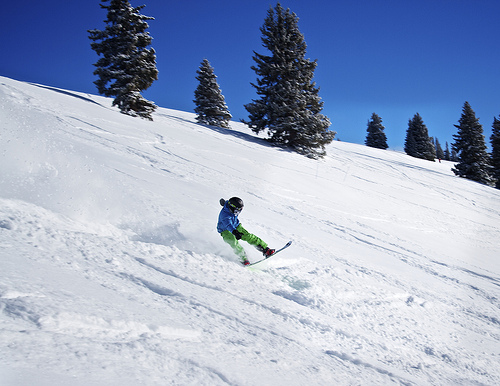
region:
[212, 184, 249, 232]
person is wearing helmet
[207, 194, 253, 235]
person's jacket is blue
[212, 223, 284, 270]
person's pants are green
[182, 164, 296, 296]
person is snowboarding downhill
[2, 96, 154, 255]
snow is being tossed in air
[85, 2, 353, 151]
trees are covered in snow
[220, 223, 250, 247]
person wearing black gloves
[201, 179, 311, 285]
person is leaning backwards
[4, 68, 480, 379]
ground is covered in snow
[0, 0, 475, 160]
the sky is clear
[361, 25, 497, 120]
the sky is cloudless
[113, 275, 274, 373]
the snow is white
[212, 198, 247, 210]
the helmet is black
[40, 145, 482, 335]
the slope is sloppy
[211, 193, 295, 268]
one leg is up in the air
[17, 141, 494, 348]
the hill is covered with snow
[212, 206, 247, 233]
the top is blue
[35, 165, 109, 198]
there is snow in the air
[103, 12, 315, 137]
trees are covered with snow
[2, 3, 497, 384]
the season is winter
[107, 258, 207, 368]
The snow is white.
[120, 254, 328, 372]
The snow is white.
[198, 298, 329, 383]
The snow is white.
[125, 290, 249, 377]
The snow is white.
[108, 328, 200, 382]
The snow is white.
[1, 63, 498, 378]
The snow is white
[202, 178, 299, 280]
Snowboarder is snowboarding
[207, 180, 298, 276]
Snowboarder wearing bright green pants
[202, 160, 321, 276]
Snowboarder wearing black helmet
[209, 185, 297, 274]
Snowboarder wearing blue jacket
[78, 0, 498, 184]
Trees on the slope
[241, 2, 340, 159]
The tree is large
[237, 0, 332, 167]
The large tree is green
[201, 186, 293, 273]
Snowboarder on the slope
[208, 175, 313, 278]
Snowboarder wearing red boots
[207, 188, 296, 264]
snowboarder in green pants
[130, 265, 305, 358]
snowboard tracks in the snow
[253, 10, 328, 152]
tree covered in snow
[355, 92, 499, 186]
many trees in a line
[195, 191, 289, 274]
snowboarder wearing black helmet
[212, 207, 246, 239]
snowboarder wearing blue jacket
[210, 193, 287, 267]
snowboarder on the snow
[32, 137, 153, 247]
flurry of snow behind snowboarder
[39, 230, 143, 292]
clumps of white snow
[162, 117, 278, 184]
smooth white snow in background